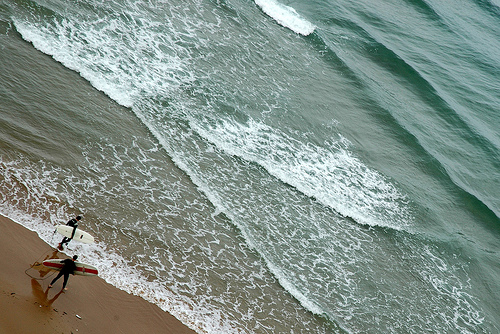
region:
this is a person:
[41, 250, 86, 298]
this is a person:
[37, 208, 96, 257]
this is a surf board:
[48, 214, 110, 251]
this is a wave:
[12, 163, 121, 252]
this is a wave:
[109, 219, 231, 318]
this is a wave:
[184, 153, 311, 290]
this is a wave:
[47, 17, 180, 129]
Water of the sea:
[207, 107, 357, 225]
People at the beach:
[34, 212, 111, 296]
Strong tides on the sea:
[387, 72, 475, 201]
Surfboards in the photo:
[59, 223, 103, 285]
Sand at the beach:
[102, 278, 170, 320]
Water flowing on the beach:
[247, 122, 359, 221]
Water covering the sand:
[209, 137, 324, 297]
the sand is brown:
[104, 296, 142, 328]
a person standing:
[41, 246, 98, 297]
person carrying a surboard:
[48, 210, 94, 252]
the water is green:
[345, 60, 468, 159]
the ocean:
[214, 111, 404, 236]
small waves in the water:
[351, 67, 392, 117]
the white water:
[274, 8, 314, 35]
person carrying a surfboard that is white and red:
[36, 250, 99, 283]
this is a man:
[37, 245, 107, 291]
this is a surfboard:
[63, 228, 98, 243]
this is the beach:
[65, 291, 127, 331]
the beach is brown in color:
[79, 300, 134, 327]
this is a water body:
[293, 30, 483, 117]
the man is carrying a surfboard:
[39, 249, 91, 294]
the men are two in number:
[46, 214, 87, 294]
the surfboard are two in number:
[46, 222, 89, 272]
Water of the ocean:
[175, 73, 367, 230]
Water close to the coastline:
[269, 117, 406, 234]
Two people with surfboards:
[19, 215, 106, 295]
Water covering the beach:
[79, 174, 161, 281]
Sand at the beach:
[92, 297, 136, 322]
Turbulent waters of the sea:
[362, 83, 455, 210]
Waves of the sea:
[340, 62, 460, 187]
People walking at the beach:
[22, 197, 98, 299]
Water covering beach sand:
[91, 156, 193, 286]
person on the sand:
[36, 250, 103, 299]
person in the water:
[55, 208, 85, 254]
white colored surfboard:
[51, 223, 96, 248]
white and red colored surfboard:
[42, 254, 99, 280]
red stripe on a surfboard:
[39, 257, 99, 274]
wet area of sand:
[1, 205, 201, 332]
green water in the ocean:
[1, 0, 499, 332]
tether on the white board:
[48, 225, 58, 252]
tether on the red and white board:
[24, 260, 56, 282]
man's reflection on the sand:
[38, 278, 67, 317]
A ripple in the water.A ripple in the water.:
[315, 39, 498, 264]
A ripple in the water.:
[414, 101, 436, 136]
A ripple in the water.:
[390, 43, 415, 75]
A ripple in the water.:
[418, 5, 457, 37]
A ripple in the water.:
[293, 195, 360, 227]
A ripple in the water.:
[236, 150, 291, 185]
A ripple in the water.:
[251, 260, 334, 312]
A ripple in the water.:
[197, 190, 264, 236]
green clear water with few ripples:
[275, 1, 499, 288]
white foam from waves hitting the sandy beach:
[3, 2, 487, 332]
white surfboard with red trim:
[38, 255, 100, 277]